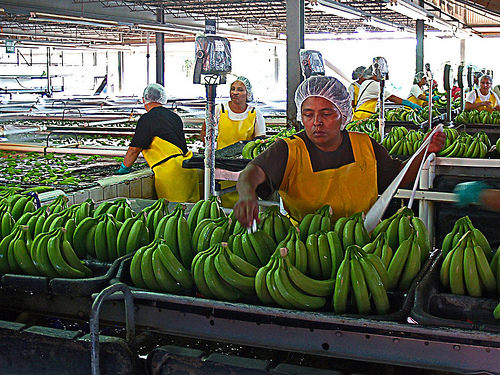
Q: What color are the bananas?
A: Green.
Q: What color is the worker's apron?
A: Yellow.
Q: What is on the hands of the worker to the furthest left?
A: Gloves.